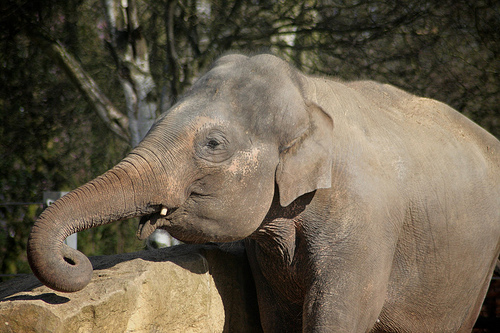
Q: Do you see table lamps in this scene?
A: No, there are no table lamps.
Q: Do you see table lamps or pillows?
A: No, there are no table lamps or pillows.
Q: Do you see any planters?
A: No, there are no planters.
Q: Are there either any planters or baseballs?
A: No, there are no planters or baseballs.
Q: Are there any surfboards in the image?
A: No, there are no surfboards.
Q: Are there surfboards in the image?
A: No, there are no surfboards.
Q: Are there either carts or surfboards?
A: No, there are no surfboards or carts.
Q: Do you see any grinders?
A: No, there are no grinders.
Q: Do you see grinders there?
A: No, there are no grinders.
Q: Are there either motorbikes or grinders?
A: No, there are no grinders or motorbikes.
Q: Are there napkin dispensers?
A: No, there are no napkin dispensers.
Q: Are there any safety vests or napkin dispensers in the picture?
A: No, there are no napkin dispensers or safety vests.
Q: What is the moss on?
A: The moss is on the branch.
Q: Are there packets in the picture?
A: No, there are no packets.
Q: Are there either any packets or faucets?
A: No, there are no packets or faucets.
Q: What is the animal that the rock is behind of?
A: The animal is an elephant.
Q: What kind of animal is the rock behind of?
A: The rock is behind the elephant.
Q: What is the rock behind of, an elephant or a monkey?
A: The rock is behind an elephant.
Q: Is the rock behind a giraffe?
A: No, the rock is behind the elephant.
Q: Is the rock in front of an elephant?
A: No, the rock is behind an elephant.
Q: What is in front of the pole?
A: The rock is in front of the pole.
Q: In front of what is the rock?
A: The rock is in front of the pole.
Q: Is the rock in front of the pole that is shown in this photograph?
A: Yes, the rock is in front of the pole.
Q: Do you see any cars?
A: No, there are no cars.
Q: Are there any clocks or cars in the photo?
A: No, there are no cars or clocks.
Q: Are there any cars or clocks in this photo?
A: No, there are no cars or clocks.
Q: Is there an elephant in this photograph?
A: Yes, there is an elephant.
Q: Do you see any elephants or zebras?
A: Yes, there is an elephant.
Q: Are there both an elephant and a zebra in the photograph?
A: No, there is an elephant but no zebras.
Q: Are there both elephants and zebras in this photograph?
A: No, there is an elephant but no zebras.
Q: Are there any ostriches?
A: No, there are no ostriches.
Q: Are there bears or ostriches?
A: No, there are no ostriches or bears.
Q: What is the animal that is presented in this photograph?
A: The animal is an elephant.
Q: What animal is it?
A: The animal is an elephant.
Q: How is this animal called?
A: This is an elephant.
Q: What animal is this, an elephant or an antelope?
A: This is an elephant.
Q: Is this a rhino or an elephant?
A: This is an elephant.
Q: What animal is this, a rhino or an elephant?
A: This is an elephant.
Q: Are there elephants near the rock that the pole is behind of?
A: Yes, there is an elephant near the rock.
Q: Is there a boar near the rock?
A: No, there is an elephant near the rock.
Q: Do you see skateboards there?
A: No, there are no skateboards.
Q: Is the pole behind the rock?
A: Yes, the pole is behind the rock.